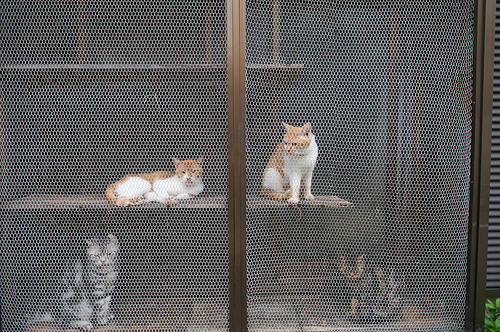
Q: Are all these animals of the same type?
A: Yes, all the animals are cats.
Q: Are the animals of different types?
A: No, all the animals are cats.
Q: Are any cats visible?
A: Yes, there is a cat.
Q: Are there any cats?
A: Yes, there is a cat.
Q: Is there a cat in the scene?
A: Yes, there is a cat.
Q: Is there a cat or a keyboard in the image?
A: Yes, there is a cat.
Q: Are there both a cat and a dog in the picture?
A: No, there is a cat but no dogs.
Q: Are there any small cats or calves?
A: Yes, there is a small cat.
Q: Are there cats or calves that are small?
A: Yes, the cat is small.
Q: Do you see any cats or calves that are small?
A: Yes, the cat is small.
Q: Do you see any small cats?
A: Yes, there is a small cat.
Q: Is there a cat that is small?
A: Yes, there is a cat that is small.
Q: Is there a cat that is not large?
A: Yes, there is a small cat.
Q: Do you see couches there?
A: No, there are no couches.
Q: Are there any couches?
A: No, there are no couches.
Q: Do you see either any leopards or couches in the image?
A: No, there are no couches or leopards.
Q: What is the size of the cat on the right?
A: The cat is small.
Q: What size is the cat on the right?
A: The cat is small.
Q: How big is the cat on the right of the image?
A: The cat is small.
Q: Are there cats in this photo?
A: Yes, there is a cat.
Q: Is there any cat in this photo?
A: Yes, there is a cat.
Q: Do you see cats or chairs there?
A: Yes, there is a cat.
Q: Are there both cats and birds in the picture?
A: No, there is a cat but no birds.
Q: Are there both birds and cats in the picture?
A: No, there is a cat but no birds.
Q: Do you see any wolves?
A: No, there are no wolves.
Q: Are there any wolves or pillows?
A: No, there are no wolves or pillows.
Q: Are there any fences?
A: Yes, there is a fence.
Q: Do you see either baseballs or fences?
A: Yes, there is a fence.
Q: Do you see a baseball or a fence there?
A: Yes, there is a fence.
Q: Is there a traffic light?
A: No, there are no traffic lights.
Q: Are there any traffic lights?
A: No, there are no traffic lights.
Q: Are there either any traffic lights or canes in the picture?
A: No, there are no traffic lights or canes.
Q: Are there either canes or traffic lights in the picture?
A: No, there are no traffic lights or canes.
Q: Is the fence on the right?
A: Yes, the fence is on the right of the image.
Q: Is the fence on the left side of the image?
A: No, the fence is on the right of the image.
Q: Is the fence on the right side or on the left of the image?
A: The fence is on the right of the image.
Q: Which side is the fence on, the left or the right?
A: The fence is on the right of the image.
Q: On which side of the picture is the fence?
A: The fence is on the right of the image.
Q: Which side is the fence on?
A: The fence is on the right of the image.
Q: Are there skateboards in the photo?
A: No, there are no skateboards.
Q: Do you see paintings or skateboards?
A: No, there are no skateboards or paintings.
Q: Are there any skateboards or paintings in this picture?
A: No, there are no skateboards or paintings.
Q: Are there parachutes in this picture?
A: No, there are no parachutes.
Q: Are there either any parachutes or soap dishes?
A: No, there are no parachutes or soap dishes.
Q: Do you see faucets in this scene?
A: No, there are no faucets.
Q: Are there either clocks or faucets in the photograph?
A: No, there are no faucets or clocks.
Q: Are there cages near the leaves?
A: Yes, there is a cage near the leaves.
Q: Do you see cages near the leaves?
A: Yes, there is a cage near the leaves.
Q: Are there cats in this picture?
A: Yes, there is a cat.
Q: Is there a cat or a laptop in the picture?
A: Yes, there is a cat.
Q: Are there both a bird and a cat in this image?
A: No, there is a cat but no birds.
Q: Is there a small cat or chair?
A: Yes, there is a small cat.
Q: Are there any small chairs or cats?
A: Yes, there is a small cat.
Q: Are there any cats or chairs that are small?
A: Yes, the cat is small.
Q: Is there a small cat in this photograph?
A: Yes, there is a small cat.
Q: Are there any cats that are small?
A: Yes, there is a cat that is small.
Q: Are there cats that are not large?
A: Yes, there is a small cat.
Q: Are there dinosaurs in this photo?
A: No, there are no dinosaurs.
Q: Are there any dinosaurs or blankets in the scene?
A: No, there are no dinosaurs or blankets.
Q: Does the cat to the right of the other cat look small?
A: Yes, the cat is small.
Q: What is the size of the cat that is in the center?
A: The cat is small.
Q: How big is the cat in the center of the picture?
A: The cat is small.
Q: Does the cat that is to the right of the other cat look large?
A: No, the cat is small.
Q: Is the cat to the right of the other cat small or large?
A: The cat is small.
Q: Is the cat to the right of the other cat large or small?
A: The cat is small.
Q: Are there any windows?
A: Yes, there is a window.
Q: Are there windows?
A: Yes, there is a window.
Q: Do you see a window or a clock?
A: Yes, there is a window.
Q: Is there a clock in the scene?
A: No, there are no clocks.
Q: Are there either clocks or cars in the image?
A: No, there are no clocks or cars.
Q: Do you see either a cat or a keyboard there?
A: Yes, there is a cat.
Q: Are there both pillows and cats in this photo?
A: No, there is a cat but no pillows.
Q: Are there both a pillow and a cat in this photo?
A: No, there is a cat but no pillows.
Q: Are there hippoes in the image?
A: No, there are no hippoes.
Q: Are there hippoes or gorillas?
A: No, there are no hippoes or gorillas.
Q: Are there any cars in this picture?
A: No, there are no cars.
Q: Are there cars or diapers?
A: No, there are no cars or diapers.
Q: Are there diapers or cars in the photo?
A: No, there are no cars or diapers.